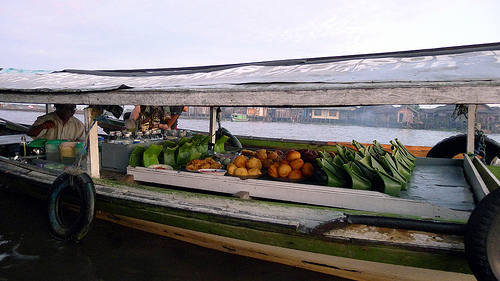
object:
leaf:
[355, 150, 403, 197]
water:
[493, 135, 500, 142]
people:
[123, 105, 150, 121]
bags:
[316, 157, 348, 187]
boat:
[231, 114, 250, 122]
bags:
[355, 150, 403, 197]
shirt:
[32, 110, 86, 142]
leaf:
[342, 161, 372, 191]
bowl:
[198, 169, 228, 176]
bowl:
[226, 170, 267, 179]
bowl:
[275, 177, 308, 183]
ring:
[44, 170, 96, 244]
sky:
[0, 0, 500, 70]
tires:
[43, 169, 97, 244]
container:
[74, 142, 86, 163]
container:
[45, 139, 71, 163]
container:
[59, 142, 86, 165]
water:
[401, 135, 410, 143]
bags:
[342, 161, 372, 190]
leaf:
[380, 152, 408, 191]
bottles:
[133, 132, 146, 145]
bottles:
[107, 131, 117, 143]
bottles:
[115, 132, 123, 144]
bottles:
[122, 134, 133, 146]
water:
[334, 129, 354, 136]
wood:
[245, 205, 303, 227]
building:
[352, 105, 395, 122]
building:
[246, 107, 269, 121]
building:
[268, 108, 305, 122]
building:
[303, 107, 356, 122]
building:
[375, 106, 419, 123]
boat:
[0, 41, 500, 280]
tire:
[462, 187, 500, 281]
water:
[420, 131, 434, 146]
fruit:
[186, 148, 336, 179]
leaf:
[394, 138, 417, 167]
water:
[375, 130, 391, 140]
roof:
[0, 42, 497, 93]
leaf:
[316, 158, 347, 188]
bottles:
[124, 131, 136, 139]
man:
[27, 104, 86, 167]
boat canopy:
[0, 42, 500, 107]